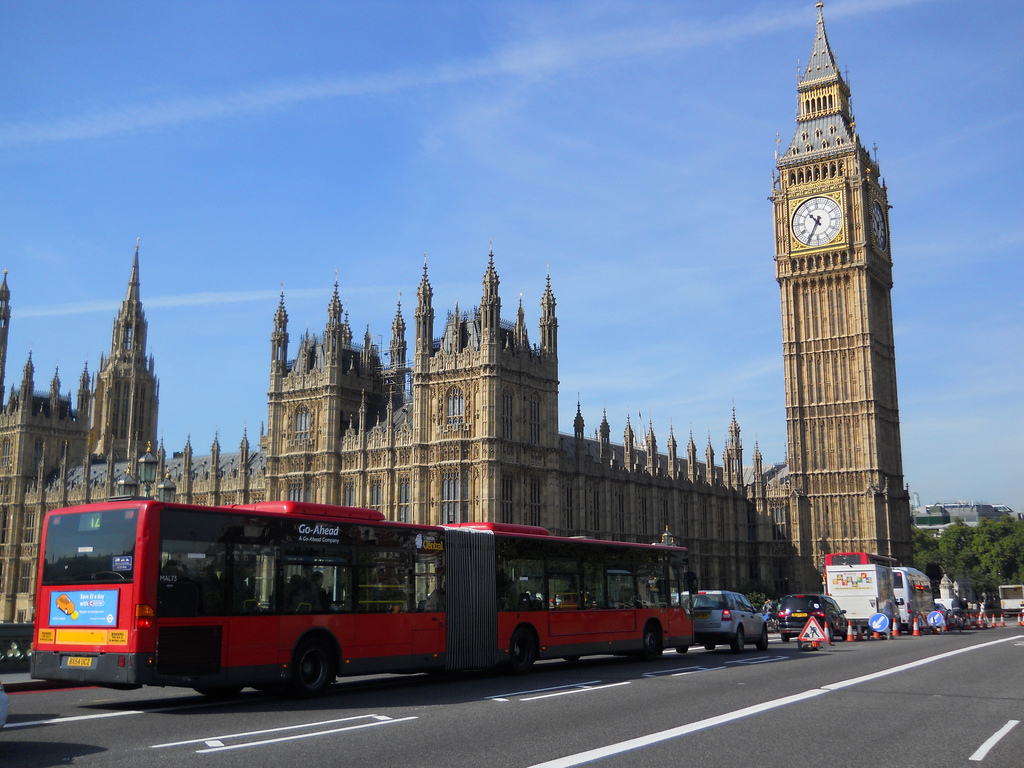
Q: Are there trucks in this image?
A: Yes, there is a truck.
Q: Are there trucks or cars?
A: Yes, there is a truck.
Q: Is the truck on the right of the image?
A: Yes, the truck is on the right of the image.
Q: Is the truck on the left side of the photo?
A: No, the truck is on the right of the image.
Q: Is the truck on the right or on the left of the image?
A: The truck is on the right of the image.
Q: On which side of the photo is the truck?
A: The truck is on the right of the image.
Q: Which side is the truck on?
A: The truck is on the right of the image.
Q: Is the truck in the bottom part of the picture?
A: Yes, the truck is in the bottom of the image.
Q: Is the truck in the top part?
A: No, the truck is in the bottom of the image.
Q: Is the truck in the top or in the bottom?
A: The truck is in the bottom of the image.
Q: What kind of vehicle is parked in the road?
A: The vehicle is a truck.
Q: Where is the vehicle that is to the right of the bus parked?
A: The truck is parked in the road.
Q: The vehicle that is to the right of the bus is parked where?
A: The truck is parked in the road.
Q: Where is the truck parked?
A: The truck is parked in the road.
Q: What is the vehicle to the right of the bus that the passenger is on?
A: The vehicle is a truck.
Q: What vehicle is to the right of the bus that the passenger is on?
A: The vehicle is a truck.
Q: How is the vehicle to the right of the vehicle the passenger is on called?
A: The vehicle is a truck.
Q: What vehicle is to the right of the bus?
A: The vehicle is a truck.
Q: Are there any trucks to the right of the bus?
A: Yes, there is a truck to the right of the bus.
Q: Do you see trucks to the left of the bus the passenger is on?
A: No, the truck is to the right of the bus.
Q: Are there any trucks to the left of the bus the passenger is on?
A: No, the truck is to the right of the bus.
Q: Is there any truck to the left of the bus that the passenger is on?
A: No, the truck is to the right of the bus.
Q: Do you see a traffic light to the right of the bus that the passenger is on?
A: No, there is a truck to the right of the bus.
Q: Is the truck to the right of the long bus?
A: Yes, the truck is to the right of the bus.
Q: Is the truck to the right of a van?
A: No, the truck is to the right of the bus.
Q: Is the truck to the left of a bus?
A: No, the truck is to the right of a bus.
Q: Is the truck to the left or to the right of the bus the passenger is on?
A: The truck is to the right of the bus.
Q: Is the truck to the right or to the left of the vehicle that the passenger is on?
A: The truck is to the right of the bus.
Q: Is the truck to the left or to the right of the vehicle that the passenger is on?
A: The truck is to the right of the bus.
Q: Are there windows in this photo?
A: Yes, there is a window.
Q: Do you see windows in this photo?
A: Yes, there is a window.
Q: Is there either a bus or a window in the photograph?
A: Yes, there is a window.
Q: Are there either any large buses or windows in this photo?
A: Yes, there is a large window.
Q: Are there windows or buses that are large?
A: Yes, the window is large.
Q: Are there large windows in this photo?
A: Yes, there is a large window.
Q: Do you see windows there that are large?
A: Yes, there is a window that is large.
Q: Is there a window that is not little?
A: Yes, there is a large window.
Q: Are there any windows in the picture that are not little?
A: Yes, there is a large window.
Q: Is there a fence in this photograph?
A: No, there are no fences.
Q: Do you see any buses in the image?
A: Yes, there is a bus.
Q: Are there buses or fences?
A: Yes, there is a bus.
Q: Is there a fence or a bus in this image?
A: Yes, there is a bus.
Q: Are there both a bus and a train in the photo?
A: No, there is a bus but no trains.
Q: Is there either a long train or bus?
A: Yes, there is a long bus.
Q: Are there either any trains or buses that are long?
A: Yes, the bus is long.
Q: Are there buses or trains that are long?
A: Yes, the bus is long.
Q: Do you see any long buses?
A: Yes, there is a long bus.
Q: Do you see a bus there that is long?
A: Yes, there is a bus that is long.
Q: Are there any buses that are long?
A: Yes, there is a bus that is long.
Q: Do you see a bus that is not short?
A: Yes, there is a long bus.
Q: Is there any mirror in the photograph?
A: No, there are no mirrors.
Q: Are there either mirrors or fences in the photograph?
A: No, there are no mirrors or fences.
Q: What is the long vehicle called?
A: The vehicle is a bus.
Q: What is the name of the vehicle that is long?
A: The vehicle is a bus.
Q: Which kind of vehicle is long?
A: The vehicle is a bus.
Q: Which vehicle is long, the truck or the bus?
A: The bus is long.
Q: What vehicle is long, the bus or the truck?
A: The bus is long.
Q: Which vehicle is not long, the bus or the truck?
A: The truck is not long.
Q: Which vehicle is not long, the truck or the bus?
A: The truck is not long.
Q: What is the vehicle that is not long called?
A: The vehicle is a truck.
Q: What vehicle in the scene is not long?
A: The vehicle is a truck.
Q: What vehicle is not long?
A: The vehicle is a truck.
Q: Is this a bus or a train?
A: This is a bus.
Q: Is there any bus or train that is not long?
A: No, there is a bus but it is long.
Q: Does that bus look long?
A: Yes, the bus is long.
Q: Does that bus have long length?
A: Yes, the bus is long.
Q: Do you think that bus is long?
A: Yes, the bus is long.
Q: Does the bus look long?
A: Yes, the bus is long.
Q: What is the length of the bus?
A: The bus is long.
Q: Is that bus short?
A: No, the bus is long.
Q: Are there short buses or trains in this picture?
A: No, there is a bus but it is long.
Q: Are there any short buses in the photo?
A: No, there is a bus but it is long.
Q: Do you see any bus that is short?
A: No, there is a bus but it is long.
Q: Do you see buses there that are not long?
A: No, there is a bus but it is long.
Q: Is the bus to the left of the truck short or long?
A: The bus is long.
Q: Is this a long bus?
A: Yes, this is a long bus.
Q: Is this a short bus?
A: No, this is a long bus.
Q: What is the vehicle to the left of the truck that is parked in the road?
A: The vehicle is a bus.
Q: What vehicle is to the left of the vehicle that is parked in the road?
A: The vehicle is a bus.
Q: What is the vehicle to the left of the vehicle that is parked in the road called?
A: The vehicle is a bus.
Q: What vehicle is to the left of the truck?
A: The vehicle is a bus.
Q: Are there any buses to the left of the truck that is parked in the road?
A: Yes, there is a bus to the left of the truck.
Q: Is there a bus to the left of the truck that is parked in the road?
A: Yes, there is a bus to the left of the truck.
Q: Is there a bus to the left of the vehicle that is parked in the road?
A: Yes, there is a bus to the left of the truck.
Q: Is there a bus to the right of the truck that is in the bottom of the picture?
A: No, the bus is to the left of the truck.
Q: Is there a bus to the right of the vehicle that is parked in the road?
A: No, the bus is to the left of the truck.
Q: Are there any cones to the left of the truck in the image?
A: No, there is a bus to the left of the truck.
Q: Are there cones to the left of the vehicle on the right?
A: No, there is a bus to the left of the truck.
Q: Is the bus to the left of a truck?
A: Yes, the bus is to the left of a truck.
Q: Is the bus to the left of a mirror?
A: No, the bus is to the left of a truck.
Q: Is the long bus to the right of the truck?
A: No, the bus is to the left of the truck.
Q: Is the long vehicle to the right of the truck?
A: No, the bus is to the left of the truck.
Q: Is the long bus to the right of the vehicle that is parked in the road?
A: No, the bus is to the left of the truck.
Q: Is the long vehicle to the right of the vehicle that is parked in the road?
A: No, the bus is to the left of the truck.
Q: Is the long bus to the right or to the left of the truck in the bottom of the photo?
A: The bus is to the left of the truck.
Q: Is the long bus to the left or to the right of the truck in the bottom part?
A: The bus is to the left of the truck.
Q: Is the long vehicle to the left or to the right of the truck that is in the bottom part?
A: The bus is to the left of the truck.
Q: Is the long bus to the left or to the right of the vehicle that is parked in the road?
A: The bus is to the left of the truck.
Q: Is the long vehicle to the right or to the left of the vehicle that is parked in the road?
A: The bus is to the left of the truck.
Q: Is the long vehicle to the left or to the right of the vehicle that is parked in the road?
A: The bus is to the left of the truck.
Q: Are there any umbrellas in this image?
A: No, there are no umbrellas.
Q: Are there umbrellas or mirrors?
A: No, there are no umbrellas or mirrors.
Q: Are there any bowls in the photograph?
A: No, there are no bowls.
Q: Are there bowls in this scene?
A: No, there are no bowls.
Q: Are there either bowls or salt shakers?
A: No, there are no bowls or salt shakers.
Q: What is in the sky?
A: The clouds are in the sky.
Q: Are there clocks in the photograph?
A: Yes, there is a clock.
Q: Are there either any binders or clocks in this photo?
A: Yes, there is a clock.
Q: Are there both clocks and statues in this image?
A: No, there is a clock but no statues.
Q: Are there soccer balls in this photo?
A: No, there are no soccer balls.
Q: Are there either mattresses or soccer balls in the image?
A: No, there are no soccer balls or mattresses.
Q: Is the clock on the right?
A: Yes, the clock is on the right of the image.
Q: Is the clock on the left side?
A: No, the clock is on the right of the image.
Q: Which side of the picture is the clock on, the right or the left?
A: The clock is on the right of the image.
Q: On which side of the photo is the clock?
A: The clock is on the right of the image.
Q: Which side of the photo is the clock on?
A: The clock is on the right of the image.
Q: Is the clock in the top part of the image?
A: Yes, the clock is in the top of the image.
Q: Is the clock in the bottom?
A: No, the clock is in the top of the image.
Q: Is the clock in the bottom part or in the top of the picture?
A: The clock is in the top of the image.